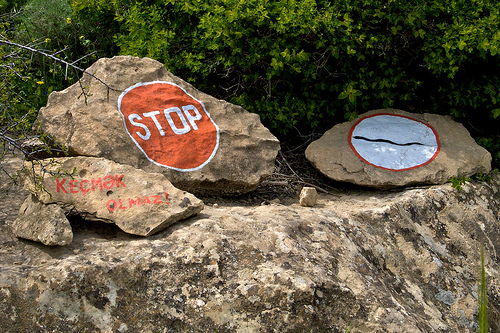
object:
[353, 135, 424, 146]
image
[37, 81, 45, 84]
flower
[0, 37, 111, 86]
woods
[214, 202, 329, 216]
ground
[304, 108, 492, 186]
rock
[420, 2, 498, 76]
bushes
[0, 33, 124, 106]
plant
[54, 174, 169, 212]
graffiti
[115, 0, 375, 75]
trees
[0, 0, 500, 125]
background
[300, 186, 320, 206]
chip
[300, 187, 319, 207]
rock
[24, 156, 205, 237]
rock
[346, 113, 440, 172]
sign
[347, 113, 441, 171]
circle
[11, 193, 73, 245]
rock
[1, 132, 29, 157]
branch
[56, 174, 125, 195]
writing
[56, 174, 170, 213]
artist name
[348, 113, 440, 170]
art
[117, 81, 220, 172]
art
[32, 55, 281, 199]
rock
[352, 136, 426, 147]
snake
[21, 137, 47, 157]
rock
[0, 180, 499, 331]
rock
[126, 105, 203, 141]
stop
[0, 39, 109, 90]
tree branch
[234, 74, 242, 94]
branch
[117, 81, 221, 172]
stop sign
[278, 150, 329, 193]
sticks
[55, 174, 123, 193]
foreign words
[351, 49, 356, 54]
foliage